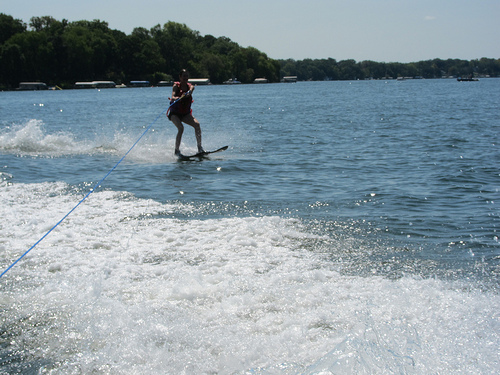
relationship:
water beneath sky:
[0, 78, 498, 374] [0, 1, 498, 65]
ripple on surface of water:
[0, 81, 500, 374] [0, 78, 498, 374]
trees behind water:
[1, 11, 285, 88] [0, 78, 498, 374]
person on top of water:
[165, 69, 210, 157] [0, 78, 498, 374]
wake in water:
[0, 180, 500, 374] [0, 78, 498, 374]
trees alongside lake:
[274, 57, 499, 82] [0, 78, 500, 374]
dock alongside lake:
[15, 81, 56, 87] [0, 78, 500, 374]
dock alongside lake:
[76, 81, 116, 90] [0, 78, 500, 374]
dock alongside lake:
[128, 79, 150, 90] [0, 78, 500, 374]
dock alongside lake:
[188, 78, 211, 87] [0, 78, 500, 374]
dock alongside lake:
[253, 78, 270, 84] [0, 78, 500, 374]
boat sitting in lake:
[454, 75, 478, 83] [0, 78, 500, 374]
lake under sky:
[0, 78, 500, 374] [0, 1, 498, 65]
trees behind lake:
[1, 11, 285, 88] [0, 78, 500, 374]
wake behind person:
[0, 117, 194, 167] [165, 69, 210, 157]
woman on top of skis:
[165, 69, 210, 157] [177, 146, 228, 163]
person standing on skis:
[165, 69, 210, 157] [177, 146, 228, 163]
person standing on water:
[165, 69, 210, 157] [0, 78, 498, 374]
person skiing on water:
[165, 69, 210, 157] [0, 78, 498, 374]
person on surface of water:
[165, 69, 210, 157] [0, 78, 498, 374]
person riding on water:
[165, 69, 210, 157] [0, 78, 498, 374]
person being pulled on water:
[165, 69, 210, 157] [0, 78, 498, 374]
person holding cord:
[165, 69, 210, 157] [0, 97, 177, 281]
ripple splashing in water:
[0, 81, 500, 374] [0, 78, 498, 374]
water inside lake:
[0, 78, 498, 374] [0, 78, 500, 374]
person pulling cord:
[165, 69, 210, 157] [0, 97, 177, 281]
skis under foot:
[177, 146, 228, 163] [197, 149, 207, 154]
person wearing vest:
[165, 69, 210, 157] [173, 81, 193, 113]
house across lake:
[472, 72, 491, 78] [0, 78, 500, 374]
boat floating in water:
[454, 75, 478, 83] [0, 78, 498, 374]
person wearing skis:
[165, 69, 210, 157] [177, 146, 228, 163]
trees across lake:
[274, 57, 499, 82] [0, 78, 500, 374]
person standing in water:
[165, 69, 210, 157] [0, 78, 498, 374]